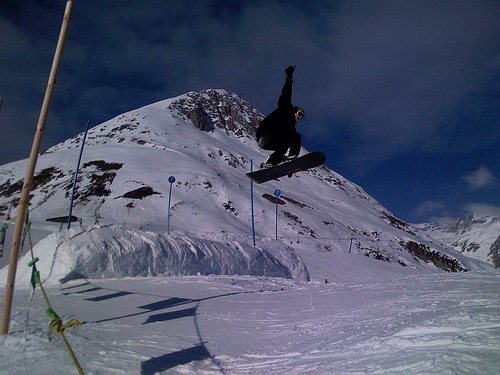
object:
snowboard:
[245, 151, 328, 185]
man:
[254, 64, 305, 168]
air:
[336, 110, 391, 129]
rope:
[34, 269, 58, 314]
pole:
[32, 57, 69, 139]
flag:
[46, 309, 77, 333]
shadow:
[138, 293, 195, 326]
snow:
[281, 302, 342, 354]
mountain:
[149, 83, 258, 182]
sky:
[160, 12, 290, 77]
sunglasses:
[296, 110, 306, 118]